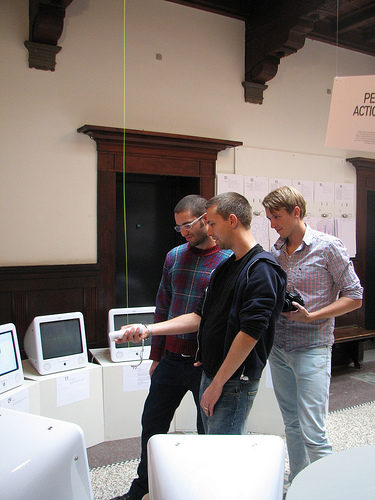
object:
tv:
[107, 306, 157, 363]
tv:
[23, 311, 88, 375]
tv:
[0, 322, 24, 395]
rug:
[90, 401, 375, 500]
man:
[261, 186, 363, 486]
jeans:
[268, 341, 333, 483]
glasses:
[174, 212, 207, 232]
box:
[22, 358, 105, 448]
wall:
[1, 0, 375, 267]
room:
[1, 1, 374, 500]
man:
[109, 194, 235, 500]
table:
[21, 358, 104, 449]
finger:
[203, 401, 209, 418]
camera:
[282, 290, 305, 312]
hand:
[280, 301, 311, 323]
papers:
[335, 183, 354, 203]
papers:
[315, 182, 334, 206]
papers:
[244, 176, 268, 203]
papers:
[218, 173, 243, 196]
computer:
[107, 306, 156, 363]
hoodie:
[195, 250, 288, 381]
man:
[113, 192, 287, 435]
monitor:
[0, 331, 19, 376]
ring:
[204, 406, 209, 410]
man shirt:
[270, 222, 363, 352]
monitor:
[114, 313, 156, 349]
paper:
[56, 372, 91, 407]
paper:
[122, 363, 150, 392]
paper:
[265, 359, 273, 389]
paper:
[5, 386, 28, 412]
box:
[88, 347, 175, 437]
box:
[243, 359, 286, 435]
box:
[0, 379, 43, 418]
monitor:
[39, 319, 83, 360]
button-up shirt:
[271, 222, 364, 352]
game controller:
[108, 323, 144, 342]